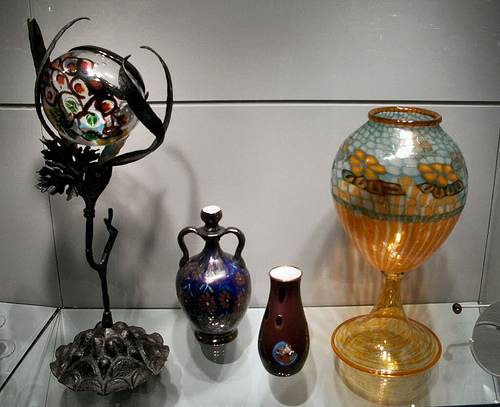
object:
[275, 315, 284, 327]
decorative holes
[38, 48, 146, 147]
glass globe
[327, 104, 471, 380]
glass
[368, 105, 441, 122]
opening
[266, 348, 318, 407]
shadow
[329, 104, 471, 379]
glass vase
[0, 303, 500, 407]
table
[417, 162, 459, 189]
flower decorations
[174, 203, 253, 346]
carafe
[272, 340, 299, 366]
decoration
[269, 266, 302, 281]
interior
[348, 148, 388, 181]
flower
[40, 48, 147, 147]
decoration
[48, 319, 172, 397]
base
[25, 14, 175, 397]
holder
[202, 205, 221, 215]
lid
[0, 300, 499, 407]
surface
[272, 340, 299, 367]
part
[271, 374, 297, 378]
edge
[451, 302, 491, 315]
bolt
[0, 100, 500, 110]
line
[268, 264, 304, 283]
top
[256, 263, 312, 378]
vase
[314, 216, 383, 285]
shadow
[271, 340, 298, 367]
circle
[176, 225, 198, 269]
handle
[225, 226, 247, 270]
handle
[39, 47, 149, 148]
ball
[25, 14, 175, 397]
stand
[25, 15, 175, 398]
art piece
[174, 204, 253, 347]
art piece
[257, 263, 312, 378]
art piece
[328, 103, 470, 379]
art piece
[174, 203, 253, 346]
vase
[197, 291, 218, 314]
flower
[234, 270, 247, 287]
flower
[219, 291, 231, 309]
flower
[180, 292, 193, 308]
flower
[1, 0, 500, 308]
wall